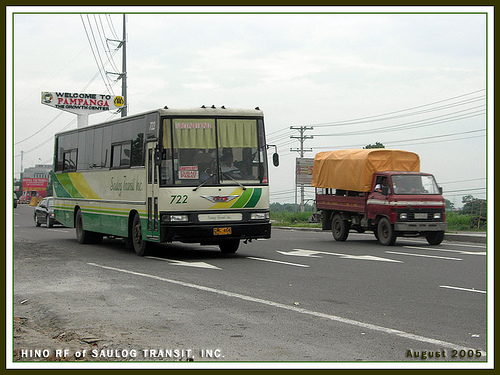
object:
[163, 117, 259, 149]
shade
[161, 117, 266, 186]
windshield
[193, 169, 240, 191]
wipers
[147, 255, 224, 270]
arrow sign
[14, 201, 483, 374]
road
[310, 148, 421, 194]
canopy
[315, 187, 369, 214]
truck bed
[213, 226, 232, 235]
license plate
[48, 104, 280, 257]
bus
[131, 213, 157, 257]
tires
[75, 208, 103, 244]
tires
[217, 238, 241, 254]
tires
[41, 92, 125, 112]
pampanga sign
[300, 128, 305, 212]
pole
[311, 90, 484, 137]
power lines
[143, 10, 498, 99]
air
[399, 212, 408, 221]
headlights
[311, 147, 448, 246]
truck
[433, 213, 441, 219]
headlights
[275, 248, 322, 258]
arrow sign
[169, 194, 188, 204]
number 722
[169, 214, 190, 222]
headlights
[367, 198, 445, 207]
stripe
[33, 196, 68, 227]
car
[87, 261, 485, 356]
lines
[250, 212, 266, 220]
headlights